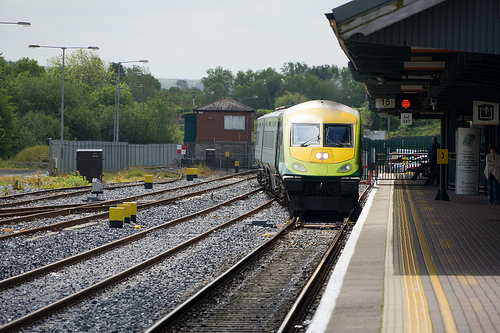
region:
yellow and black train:
[243, 96, 363, 203]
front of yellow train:
[287, 106, 361, 173]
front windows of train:
[291, 122, 352, 147]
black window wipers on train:
[297, 131, 315, 146]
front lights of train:
[310, 148, 331, 160]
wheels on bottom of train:
[252, 173, 284, 190]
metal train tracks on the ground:
[189, 243, 332, 331]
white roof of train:
[295, 100, 345, 111]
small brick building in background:
[190, 100, 257, 139]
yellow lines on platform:
[389, 209, 434, 299]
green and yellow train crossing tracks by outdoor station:
[246, 92, 497, 227]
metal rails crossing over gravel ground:
[5, 170, 350, 327]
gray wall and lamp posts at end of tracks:
[0, 16, 180, 176]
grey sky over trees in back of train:
[5, 46, 366, 137]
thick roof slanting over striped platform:
[310, 0, 495, 330]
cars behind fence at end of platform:
[361, 141, 446, 177]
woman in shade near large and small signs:
[450, 95, 495, 200]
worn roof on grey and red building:
[186, 91, 251, 158]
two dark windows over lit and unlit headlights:
[276, 100, 356, 175]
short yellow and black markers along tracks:
[102, 165, 227, 230]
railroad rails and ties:
[220, 256, 314, 317]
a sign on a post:
[435, 144, 450, 194]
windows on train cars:
[255, 127, 279, 147]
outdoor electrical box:
[66, 142, 116, 180]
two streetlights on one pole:
[25, 36, 103, 128]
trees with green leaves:
[8, 76, 55, 136]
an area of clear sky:
[142, 7, 282, 54]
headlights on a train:
[287, 157, 354, 182]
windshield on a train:
[290, 118, 357, 155]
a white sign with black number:
[375, 91, 399, 112]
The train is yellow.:
[258, 97, 365, 223]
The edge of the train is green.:
[262, 89, 367, 209]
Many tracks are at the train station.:
[24, 183, 289, 332]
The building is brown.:
[188, 111, 258, 153]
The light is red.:
[398, 96, 413, 112]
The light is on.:
[393, 93, 411, 108]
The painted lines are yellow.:
[387, 166, 442, 331]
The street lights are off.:
[10, 17, 157, 81]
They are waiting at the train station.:
[407, 129, 444, 176]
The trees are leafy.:
[4, 61, 349, 131]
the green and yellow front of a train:
[273, 97, 365, 207]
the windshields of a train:
[292, 120, 356, 153]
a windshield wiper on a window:
[303, 130, 318, 147]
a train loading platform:
[343, 179, 415, 331]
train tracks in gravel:
[68, 238, 309, 313]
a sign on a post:
[433, 145, 454, 172]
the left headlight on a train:
[338, 164, 353, 175]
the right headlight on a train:
[287, 160, 308, 176]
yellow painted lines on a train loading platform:
[394, 199, 466, 331]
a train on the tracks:
[244, 107, 368, 259]